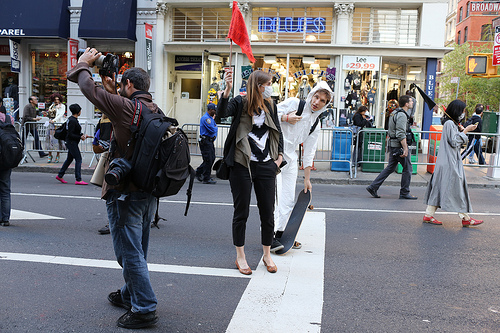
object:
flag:
[225, 1, 256, 65]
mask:
[258, 84, 273, 100]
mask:
[459, 113, 465, 121]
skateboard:
[275, 189, 314, 255]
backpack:
[108, 98, 196, 231]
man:
[64, 46, 197, 328]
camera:
[76, 48, 119, 78]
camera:
[104, 158, 132, 186]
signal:
[465, 53, 497, 78]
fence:
[0, 118, 498, 178]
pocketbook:
[213, 159, 230, 181]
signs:
[491, 17, 499, 66]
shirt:
[65, 62, 159, 201]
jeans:
[105, 191, 156, 316]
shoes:
[117, 309, 158, 328]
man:
[107, 289, 132, 310]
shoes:
[107, 288, 137, 310]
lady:
[215, 70, 288, 275]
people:
[420, 99, 484, 227]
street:
[1, 167, 500, 332]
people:
[366, 95, 419, 199]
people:
[259, 80, 334, 252]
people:
[192, 102, 218, 184]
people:
[53, 103, 88, 185]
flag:
[413, 83, 436, 111]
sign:
[257, 16, 326, 33]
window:
[245, 4, 337, 45]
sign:
[342, 55, 380, 71]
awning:
[76, 0, 137, 42]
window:
[26, 49, 138, 119]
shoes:
[462, 217, 484, 227]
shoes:
[423, 214, 443, 225]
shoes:
[262, 255, 277, 273]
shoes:
[235, 258, 253, 274]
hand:
[304, 178, 312, 194]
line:
[219, 212, 325, 333]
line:
[0, 251, 256, 278]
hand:
[468, 58, 477, 73]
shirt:
[275, 82, 332, 169]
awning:
[0, 0, 71, 42]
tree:
[433, 40, 500, 136]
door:
[174, 71, 202, 130]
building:
[155, 0, 451, 153]